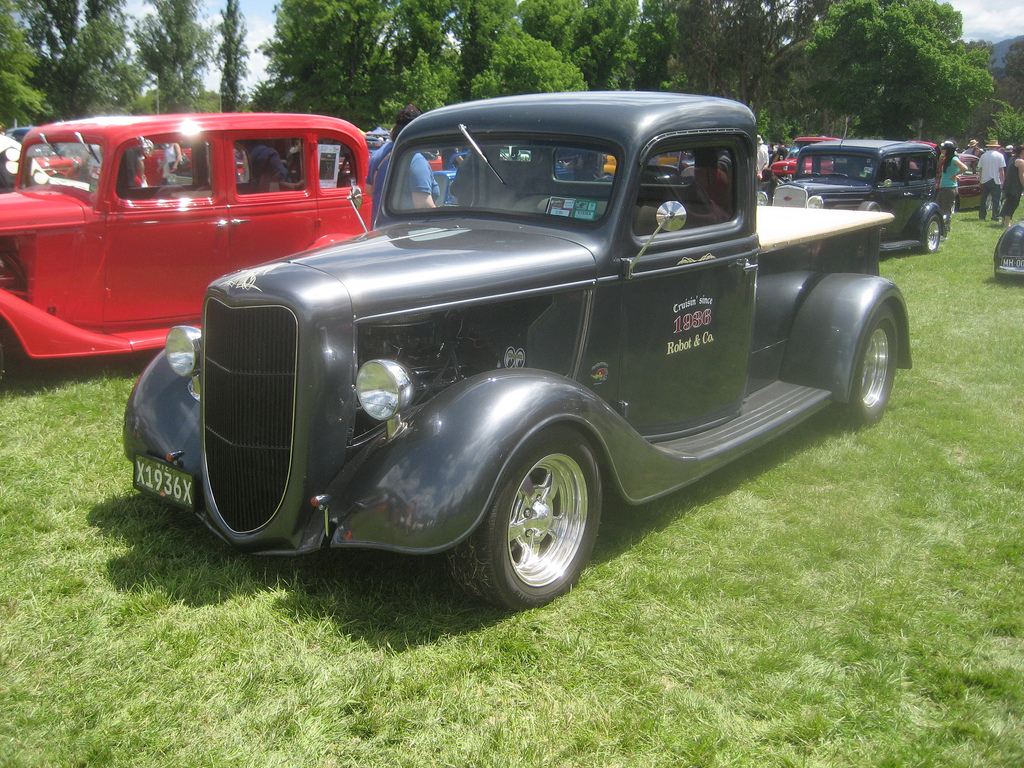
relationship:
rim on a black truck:
[502, 445, 585, 585] [121, 90, 910, 613]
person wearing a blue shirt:
[930, 139, 974, 246] [936, 161, 965, 201]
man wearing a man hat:
[966, 127, 992, 238] [966, 137, 1008, 233]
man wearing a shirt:
[966, 127, 992, 238] [964, 148, 991, 190]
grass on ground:
[2, 167, 1023, 759] [666, 509, 978, 754]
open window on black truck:
[621, 127, 749, 245] [115, 77, 917, 611]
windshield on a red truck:
[13, 140, 107, 199] [11, 96, 370, 364]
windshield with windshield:
[13, 140, 107, 199] [17, 142, 104, 194]